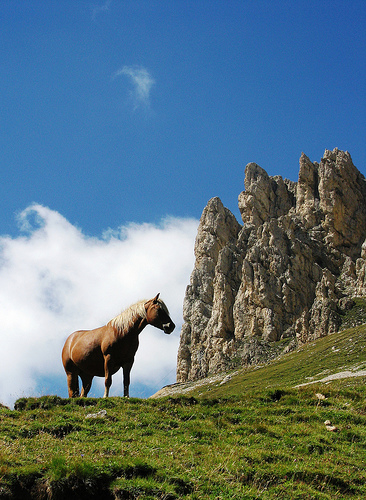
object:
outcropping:
[172, 145, 365, 380]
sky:
[0, 1, 365, 416]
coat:
[61, 289, 176, 398]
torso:
[61, 298, 146, 399]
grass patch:
[0, 324, 365, 499]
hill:
[175, 148, 365, 380]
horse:
[59, 290, 176, 397]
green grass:
[0, 321, 365, 428]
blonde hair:
[60, 291, 174, 399]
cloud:
[105, 59, 157, 123]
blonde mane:
[105, 299, 149, 337]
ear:
[151, 289, 162, 305]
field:
[0, 319, 365, 498]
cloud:
[0, 199, 200, 412]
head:
[146, 287, 176, 338]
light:
[67, 332, 78, 358]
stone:
[175, 139, 365, 387]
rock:
[322, 418, 337, 433]